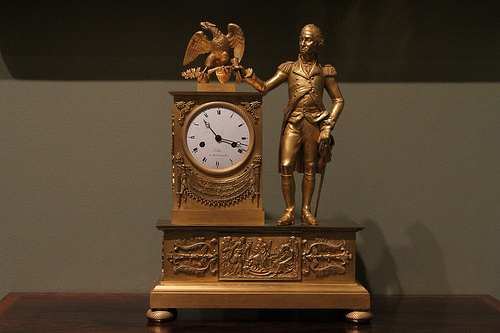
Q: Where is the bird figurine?
A: On the clock.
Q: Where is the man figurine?
A: Next to the clock.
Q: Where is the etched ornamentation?
A: Under the clock.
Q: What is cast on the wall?
A: Shadows.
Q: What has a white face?
A: The clock.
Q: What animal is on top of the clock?
A: A bird.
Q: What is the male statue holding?
A: A cane.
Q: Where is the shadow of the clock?
A: On the right.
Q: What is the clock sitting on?
A: A table.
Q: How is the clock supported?
A: It sits on a base.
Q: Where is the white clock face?
A: In the center.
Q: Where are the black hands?
A: On the clock.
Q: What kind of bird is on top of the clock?
A: An eagle.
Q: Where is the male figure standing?
A: Next to the clock.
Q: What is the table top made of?
A: Wood.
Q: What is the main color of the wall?
A: Gray.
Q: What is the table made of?
A: Wood.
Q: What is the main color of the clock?
A: Gold.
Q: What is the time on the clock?
A: 3:53.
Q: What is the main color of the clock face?
A: White.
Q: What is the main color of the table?
A: Brown.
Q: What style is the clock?
A: Patriotic.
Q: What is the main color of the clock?
A: Gold.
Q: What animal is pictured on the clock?
A: Eagle.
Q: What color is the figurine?
A: Gold.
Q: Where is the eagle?
A: On top.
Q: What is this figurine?
A: A clock.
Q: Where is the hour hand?
A: Close to XI.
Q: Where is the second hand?
A: Between the III and IV.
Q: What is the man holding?
A: A sword.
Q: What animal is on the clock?
A: Eagle.